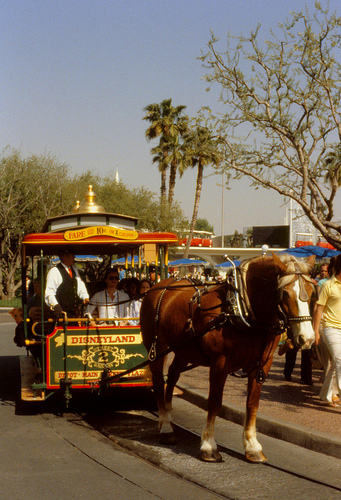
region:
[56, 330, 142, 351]
a sign that says DISNEYLAND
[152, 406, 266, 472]
white hooves on a horse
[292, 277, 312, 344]
white stripe on a horses nose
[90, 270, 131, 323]
man in the front seat of a carriage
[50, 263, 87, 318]
black dress vest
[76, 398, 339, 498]
railroad tracks on the ground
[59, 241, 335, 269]
tops of blue umbrellas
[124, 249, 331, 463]
a brown and white horse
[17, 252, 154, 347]
a bunch of people in a trolly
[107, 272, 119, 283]
black sunglasses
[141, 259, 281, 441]
the horse is brown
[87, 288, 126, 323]
the shirt is white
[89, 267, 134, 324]
the man is in glasses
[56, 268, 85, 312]
the coat is black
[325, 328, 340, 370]
the pants are white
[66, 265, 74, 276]
the tie is red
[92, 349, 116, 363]
number 2 is wriiten on the front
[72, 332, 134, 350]
disneyland letters are in red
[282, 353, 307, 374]
the pants are black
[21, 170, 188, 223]
trees are in the background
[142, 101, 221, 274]
group of three palm trees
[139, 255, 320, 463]
horse pulling a carriage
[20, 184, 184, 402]
red and green Disneyland carriage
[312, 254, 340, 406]
woman wearing a yellow shirt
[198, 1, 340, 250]
tree with sparse leaves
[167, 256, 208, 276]
large blue outdoor umbrella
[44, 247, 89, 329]
carriage operator in green vest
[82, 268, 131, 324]
man wearing sunglasses and white shirt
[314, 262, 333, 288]
man wearing blue shirt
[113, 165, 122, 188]
white tower in the distance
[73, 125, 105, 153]
this is the sky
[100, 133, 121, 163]
the sky is blue in color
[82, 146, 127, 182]
the sky has clouds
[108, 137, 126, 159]
the clouds are white in color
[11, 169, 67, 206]
this is a tree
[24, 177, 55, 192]
the leaves are green in color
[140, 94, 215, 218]
the trees are tall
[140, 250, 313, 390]
this is a horse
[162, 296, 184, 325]
the fur is brown in color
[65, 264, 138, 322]
these are some people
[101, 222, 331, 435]
a horse on the road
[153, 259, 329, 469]
a horse on the street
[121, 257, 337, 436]
a brown horse on ther oad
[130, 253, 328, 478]
a brown horse on the street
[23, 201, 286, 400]
a horse pulling a carriage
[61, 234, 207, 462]
a carriage on the road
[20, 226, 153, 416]
a carriage on the street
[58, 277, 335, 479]
a street with a horse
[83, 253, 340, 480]
a street with a brown horse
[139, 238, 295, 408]
a road with a horse